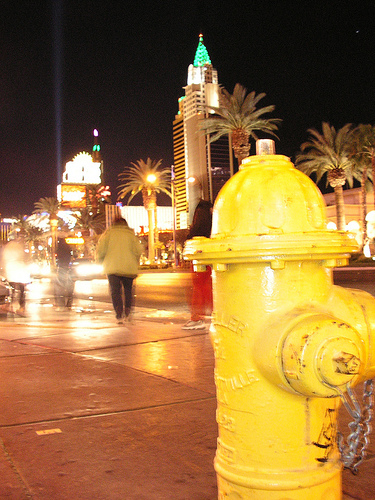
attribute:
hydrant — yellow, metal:
[200, 139, 371, 499]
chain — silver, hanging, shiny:
[342, 387, 374, 470]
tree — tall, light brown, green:
[206, 82, 267, 162]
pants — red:
[183, 254, 208, 314]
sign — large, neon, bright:
[63, 148, 107, 183]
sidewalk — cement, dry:
[3, 292, 216, 498]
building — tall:
[175, 38, 227, 231]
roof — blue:
[187, 35, 215, 69]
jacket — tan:
[102, 227, 143, 274]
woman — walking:
[95, 212, 150, 319]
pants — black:
[109, 270, 136, 313]